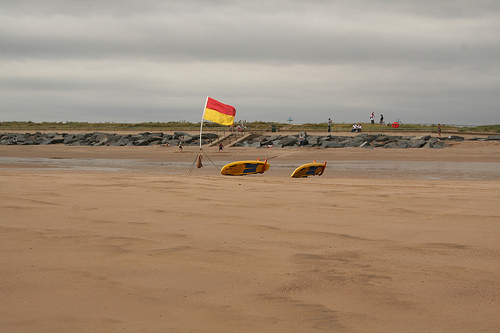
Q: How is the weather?
A: It is cloudy.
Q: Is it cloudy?
A: Yes, it is cloudy.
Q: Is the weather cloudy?
A: Yes, it is cloudy.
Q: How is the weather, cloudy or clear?
A: It is cloudy.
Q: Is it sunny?
A: No, it is cloudy.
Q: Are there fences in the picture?
A: No, there are no fences.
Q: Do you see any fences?
A: No, there are no fences.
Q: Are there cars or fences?
A: No, there are no fences or cars.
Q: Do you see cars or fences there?
A: No, there are no fences or cars.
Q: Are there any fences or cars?
A: No, there are no fences or cars.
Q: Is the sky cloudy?
A: Yes, the sky is cloudy.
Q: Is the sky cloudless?
A: No, the sky is cloudy.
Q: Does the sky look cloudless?
A: No, the sky is cloudy.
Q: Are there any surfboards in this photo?
A: Yes, there is a surfboard.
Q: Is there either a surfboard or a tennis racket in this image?
A: Yes, there is a surfboard.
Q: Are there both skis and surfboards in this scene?
A: No, there is a surfboard but no skis.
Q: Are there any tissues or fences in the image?
A: No, there are no fences or tissues.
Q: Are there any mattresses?
A: No, there are no mattresses.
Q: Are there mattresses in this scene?
A: No, there are no mattresses.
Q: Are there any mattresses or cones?
A: No, there are no mattresses or cones.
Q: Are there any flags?
A: Yes, there is a flag.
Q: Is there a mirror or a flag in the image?
A: Yes, there is a flag.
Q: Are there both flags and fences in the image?
A: No, there is a flag but no fences.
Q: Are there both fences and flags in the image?
A: No, there is a flag but no fences.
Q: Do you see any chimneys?
A: No, there are no chimneys.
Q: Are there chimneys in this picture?
A: No, there are no chimneys.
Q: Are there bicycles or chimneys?
A: No, there are no chimneys or bicycles.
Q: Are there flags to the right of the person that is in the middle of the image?
A: Yes, there is a flag to the right of the person.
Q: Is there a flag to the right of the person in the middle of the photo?
A: Yes, there is a flag to the right of the person.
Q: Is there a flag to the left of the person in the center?
A: No, the flag is to the right of the person.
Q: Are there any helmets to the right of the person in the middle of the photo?
A: No, there is a flag to the right of the person.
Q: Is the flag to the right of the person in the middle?
A: Yes, the flag is to the right of the person.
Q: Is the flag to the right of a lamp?
A: No, the flag is to the right of the person.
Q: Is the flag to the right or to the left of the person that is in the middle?
A: The flag is to the right of the person.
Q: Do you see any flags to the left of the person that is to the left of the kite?
A: Yes, there is a flag to the left of the person.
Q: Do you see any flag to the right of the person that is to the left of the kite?
A: No, the flag is to the left of the person.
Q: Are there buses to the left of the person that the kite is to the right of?
A: No, there is a flag to the left of the person.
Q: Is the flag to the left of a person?
A: Yes, the flag is to the left of a person.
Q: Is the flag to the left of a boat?
A: No, the flag is to the left of a person.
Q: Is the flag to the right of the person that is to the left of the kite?
A: No, the flag is to the left of the person.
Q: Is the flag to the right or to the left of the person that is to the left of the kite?
A: The flag is to the left of the person.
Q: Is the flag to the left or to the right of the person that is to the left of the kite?
A: The flag is to the left of the person.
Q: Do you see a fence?
A: No, there are no fences.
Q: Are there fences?
A: No, there are no fences.